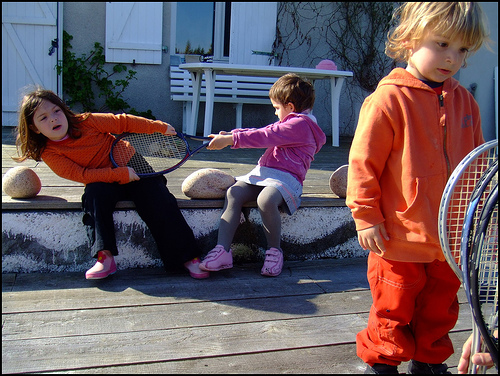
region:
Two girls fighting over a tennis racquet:
[17, 68, 343, 199]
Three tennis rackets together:
[434, 154, 498, 361]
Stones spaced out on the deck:
[1, 161, 237, 199]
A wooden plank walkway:
[47, 290, 282, 363]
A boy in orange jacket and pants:
[351, 31, 462, 328]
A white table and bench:
[163, 52, 368, 122]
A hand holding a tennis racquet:
[445, 315, 497, 371]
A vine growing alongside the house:
[50, 22, 152, 128]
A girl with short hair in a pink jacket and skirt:
[231, 70, 333, 207]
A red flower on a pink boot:
[86, 247, 122, 288]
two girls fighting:
[13, 65, 318, 282]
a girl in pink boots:
[14, 87, 204, 292]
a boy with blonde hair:
[343, 5, 498, 370]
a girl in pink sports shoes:
[186, 65, 341, 280]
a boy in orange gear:
[349, 2, 487, 373]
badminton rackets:
[436, 139, 498, 371]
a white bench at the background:
[168, 54, 353, 155]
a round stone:
[6, 167, 41, 197]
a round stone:
[176, 165, 251, 205]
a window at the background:
[101, 0, 236, 62]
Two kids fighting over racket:
[23, 53, 340, 218]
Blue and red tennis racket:
[108, 119, 215, 183]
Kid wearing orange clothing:
[353, 13, 463, 327]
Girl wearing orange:
[9, 103, 207, 287]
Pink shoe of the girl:
[76, 237, 137, 297]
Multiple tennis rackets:
[422, 138, 495, 330]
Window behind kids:
[153, 1, 262, 65]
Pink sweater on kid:
[233, 110, 330, 168]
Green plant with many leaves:
[69, 38, 139, 115]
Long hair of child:
[373, 6, 498, 91]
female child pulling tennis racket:
[195, 65, 312, 229]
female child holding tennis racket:
[13, 87, 205, 202]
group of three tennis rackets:
[449, 141, 498, 243]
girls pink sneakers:
[206, 226, 316, 273]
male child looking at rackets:
[361, 3, 488, 130]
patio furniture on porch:
[166, 51, 328, 99]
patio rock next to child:
[2, 154, 61, 197]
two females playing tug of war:
[20, 70, 298, 243]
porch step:
[8, 193, 74, 313]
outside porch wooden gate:
[3, 39, 93, 85]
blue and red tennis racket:
[108, 127, 215, 177]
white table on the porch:
[182, 59, 351, 149]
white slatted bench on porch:
[167, 59, 284, 138]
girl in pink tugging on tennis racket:
[203, 73, 324, 278]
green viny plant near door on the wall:
[56, 31, 157, 130]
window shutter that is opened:
[103, 1, 165, 64]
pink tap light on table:
[316, 59, 336, 74]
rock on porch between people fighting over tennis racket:
[183, 166, 233, 199]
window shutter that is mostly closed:
[227, 1, 278, 68]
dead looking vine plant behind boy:
[275, 1, 400, 138]